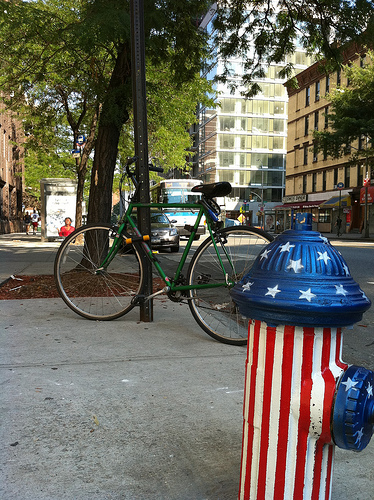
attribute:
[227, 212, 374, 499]
fire hydrant — painted, red, white, blue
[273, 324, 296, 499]
stripe — red, painted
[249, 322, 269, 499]
stripe — white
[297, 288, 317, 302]
star — painted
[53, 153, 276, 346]
bike — green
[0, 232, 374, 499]
sidewalk — dirty, concrete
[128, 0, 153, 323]
pole — black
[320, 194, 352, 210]
awning — blue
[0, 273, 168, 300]
mulch — red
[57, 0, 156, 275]
tree — leafy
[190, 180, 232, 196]
seat — black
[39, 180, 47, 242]
sign pole — concrete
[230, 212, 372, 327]
top — blue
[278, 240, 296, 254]
star — white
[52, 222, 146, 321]
tire — black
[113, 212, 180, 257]
car — silver